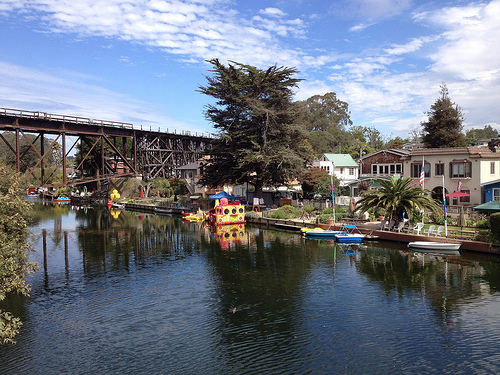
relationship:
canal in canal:
[3, 201, 499, 374] [3, 201, 499, 374]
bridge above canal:
[2, 107, 223, 192] [3, 201, 499, 374]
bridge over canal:
[2, 107, 223, 192] [3, 201, 499, 374]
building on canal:
[398, 146, 498, 224] [3, 201, 499, 374]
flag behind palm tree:
[408, 156, 428, 193] [349, 171, 443, 229]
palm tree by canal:
[349, 171, 443, 229] [3, 201, 499, 374]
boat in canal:
[207, 202, 249, 228] [3, 201, 499, 374]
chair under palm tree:
[380, 218, 398, 232] [349, 171, 443, 229]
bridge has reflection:
[2, 107, 223, 192] [27, 220, 222, 287]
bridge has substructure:
[2, 107, 223, 192] [1, 131, 217, 186]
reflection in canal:
[27, 220, 222, 287] [3, 201, 499, 374]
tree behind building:
[423, 81, 467, 150] [398, 146, 498, 224]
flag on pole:
[408, 156, 428, 193] [420, 157, 428, 222]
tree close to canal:
[195, 54, 310, 198] [3, 201, 499, 374]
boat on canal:
[207, 202, 249, 228] [3, 201, 499, 374]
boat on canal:
[407, 237, 463, 252] [3, 201, 499, 374]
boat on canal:
[304, 227, 348, 241] [3, 201, 499, 374]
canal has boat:
[3, 201, 499, 374] [207, 202, 249, 228]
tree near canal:
[195, 54, 310, 198] [3, 201, 499, 374]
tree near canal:
[1, 169, 44, 344] [3, 201, 499, 374]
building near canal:
[398, 146, 498, 224] [3, 201, 499, 374]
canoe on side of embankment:
[405, 238, 463, 252] [37, 184, 499, 258]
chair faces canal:
[380, 218, 398, 232] [3, 201, 499, 374]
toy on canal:
[208, 198, 246, 225] [3, 201, 499, 374]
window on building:
[446, 160, 476, 182] [398, 146, 498, 224]